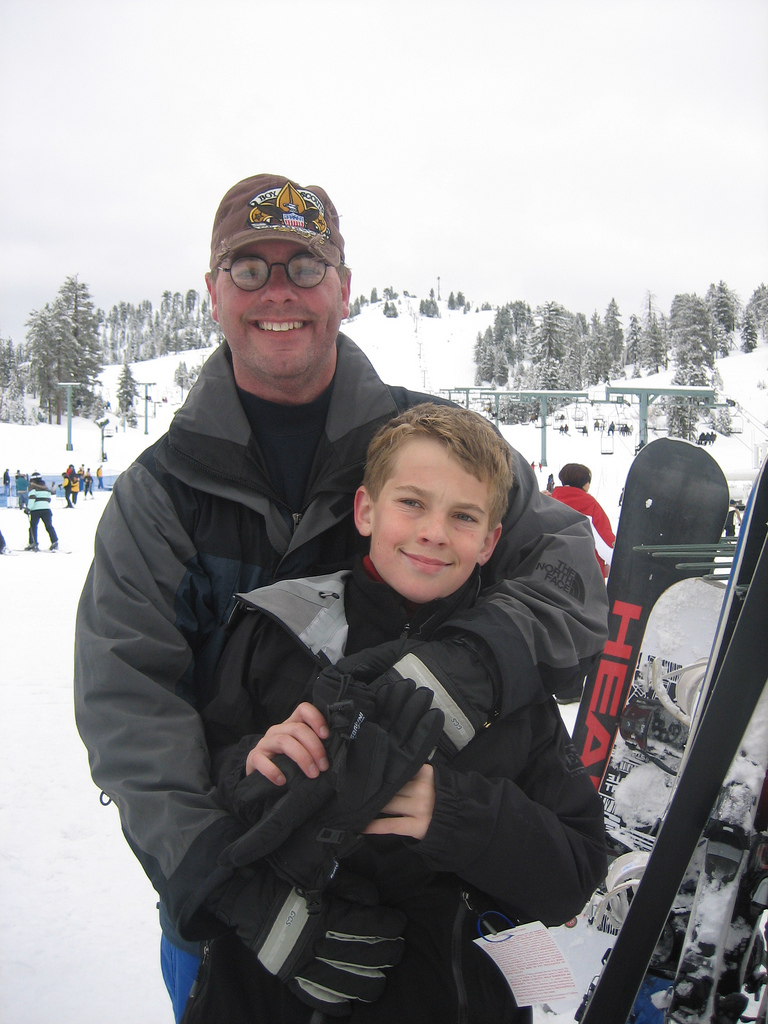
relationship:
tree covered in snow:
[475, 338, 489, 379] [475, 338, 489, 379]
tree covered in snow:
[491, 346, 509, 390] [491, 346, 509, 390]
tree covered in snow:
[644, 314, 664, 375] [644, 314, 664, 375]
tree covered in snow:
[626, 311, 646, 377] [626, 311, 646, 377]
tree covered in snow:
[600, 294, 624, 375] [600, 294, 624, 375]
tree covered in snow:
[584, 308, 612, 386] [584, 308, 612, 386]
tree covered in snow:
[733, 307, 756, 354] [733, 307, 756, 354]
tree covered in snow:
[114, 359, 133, 414] [114, 359, 133, 414]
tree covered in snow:
[528, 305, 564, 391] [528, 305, 564, 391]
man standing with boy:
[81, 173, 609, 991] [190, 403, 611, 1014]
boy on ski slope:
[190, 403, 611, 1014] [9, 331, 757, 1022]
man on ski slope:
[81, 173, 609, 991] [9, 331, 757, 1022]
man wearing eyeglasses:
[81, 173, 609, 991] [211, 250, 342, 293]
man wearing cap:
[81, 173, 609, 991] [200, 173, 347, 267]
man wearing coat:
[81, 173, 609, 991] [68, 342, 613, 957]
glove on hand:
[228, 869, 418, 1011] [228, 869, 418, 1011]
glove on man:
[228, 869, 418, 1011] [81, 173, 609, 991]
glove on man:
[298, 634, 504, 812] [81, 173, 609, 991]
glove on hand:
[298, 634, 504, 812] [298, 634, 504, 812]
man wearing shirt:
[81, 173, 609, 991] [240, 378, 342, 506]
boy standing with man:
[190, 403, 611, 1015] [81, 173, 609, 991]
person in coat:
[18, 472, 64, 555] [18, 479, 49, 511]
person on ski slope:
[18, 472, 64, 555] [9, 331, 757, 1022]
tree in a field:
[116, 363, 137, 424] [13, 342, 765, 755]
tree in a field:
[38, 283, 99, 431] [1, 294, 766, 607]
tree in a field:
[30, 301, 83, 421] [6, 310, 760, 622]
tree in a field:
[154, 293, 172, 347] [7, 301, 762, 568]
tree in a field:
[663, 323, 706, 436] [1, 294, 766, 607]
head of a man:
[197, 173, 346, 375] [81, 173, 609, 991]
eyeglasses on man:
[211, 250, 342, 293] [81, 173, 609, 991]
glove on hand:
[228, 870, 418, 1012] [208, 871, 408, 1008]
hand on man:
[208, 871, 408, 1008] [81, 173, 609, 991]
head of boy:
[348, 403, 513, 607] [190, 403, 611, 1014]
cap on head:
[200, 173, 347, 268] [197, 174, 346, 376]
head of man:
[197, 174, 346, 376] [81, 173, 609, 991]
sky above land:
[4, 2, 766, 366] [5, 288, 766, 1017]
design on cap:
[249, 182, 327, 241] [200, 173, 347, 268]